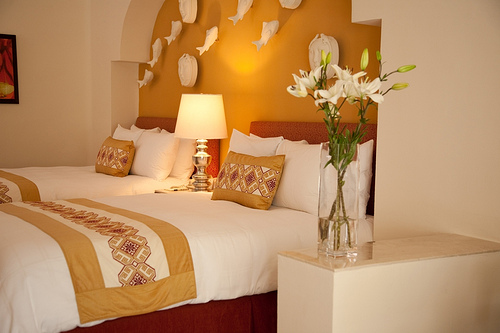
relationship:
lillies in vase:
[293, 66, 389, 108] [319, 142, 363, 262]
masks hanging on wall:
[169, 0, 212, 95] [130, 17, 322, 87]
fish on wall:
[191, 25, 222, 56] [130, 17, 322, 87]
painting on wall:
[1, 29, 22, 114] [7, 10, 91, 174]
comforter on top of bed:
[13, 192, 302, 291] [10, 196, 365, 322]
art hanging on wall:
[193, 23, 287, 52] [130, 17, 322, 87]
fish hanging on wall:
[191, 25, 222, 56] [130, 17, 322, 87]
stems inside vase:
[324, 108, 355, 219] [319, 142, 363, 262]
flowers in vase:
[305, 55, 386, 176] [319, 142, 363, 262]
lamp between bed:
[163, 91, 240, 197] [10, 194, 318, 323]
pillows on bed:
[110, 122, 204, 179] [10, 196, 365, 322]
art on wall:
[193, 23, 287, 52] [130, 17, 322, 87]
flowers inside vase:
[305, 55, 386, 176] [319, 142, 363, 262]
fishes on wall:
[147, 18, 301, 49] [130, 17, 322, 87]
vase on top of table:
[319, 142, 363, 262] [278, 245, 499, 325]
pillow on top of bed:
[214, 146, 284, 212] [10, 196, 365, 322]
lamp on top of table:
[163, 91, 240, 197] [156, 180, 195, 200]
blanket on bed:
[16, 189, 206, 306] [10, 196, 365, 322]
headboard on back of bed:
[245, 111, 406, 158] [10, 196, 365, 322]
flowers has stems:
[305, 55, 386, 176] [324, 108, 355, 219]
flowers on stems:
[305, 55, 386, 176] [324, 108, 355, 219]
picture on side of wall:
[1, 29, 22, 114] [130, 17, 322, 87]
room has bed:
[6, 1, 496, 331] [10, 194, 318, 323]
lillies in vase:
[337, 66, 386, 169] [319, 142, 363, 262]